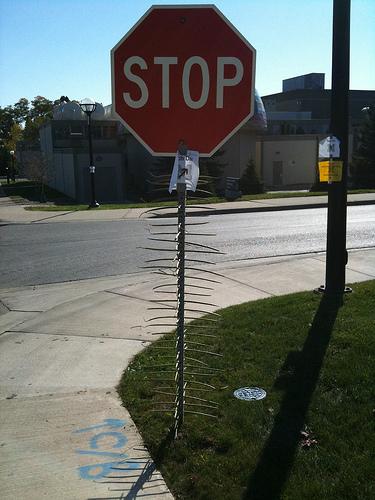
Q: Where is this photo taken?
A: An intersection.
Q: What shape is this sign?
A: Octagon.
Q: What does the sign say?
A: STOP.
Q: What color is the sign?
A: Red.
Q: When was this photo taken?
A: During the day.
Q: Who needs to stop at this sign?
A: Drivers.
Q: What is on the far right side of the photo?
A: Telephone pole.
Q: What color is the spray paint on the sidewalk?
A: Blue.